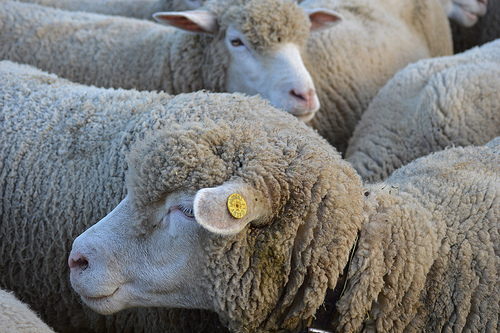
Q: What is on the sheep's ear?
A: Tag.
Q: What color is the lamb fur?
A: White.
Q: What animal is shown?
A: Lambs.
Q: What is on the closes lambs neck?
A: Folds and wrinkles.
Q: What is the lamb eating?
A: Grass.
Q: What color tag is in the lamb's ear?
A: Yellow.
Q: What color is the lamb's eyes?
A: Black.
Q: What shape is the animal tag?
A: Circular.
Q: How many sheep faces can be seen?
A: Two.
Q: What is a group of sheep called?
A: Flock.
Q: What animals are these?
A: Sheep.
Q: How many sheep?
A: Seven.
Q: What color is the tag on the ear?
A: Yellow.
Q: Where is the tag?
A: On Sheep's ear.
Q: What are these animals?
A: Sheep.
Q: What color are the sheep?
A: Beige.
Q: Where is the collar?
A: On sheeps' neck.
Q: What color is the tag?
A: Gold.